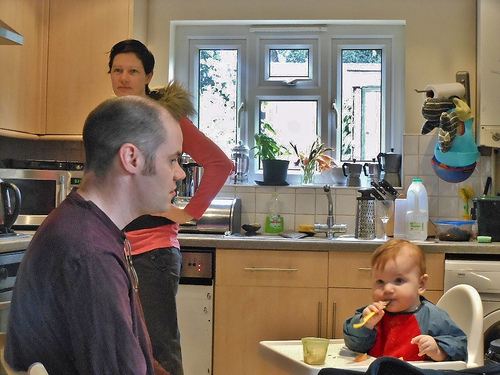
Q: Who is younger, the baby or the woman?
A: The baby is younger than the woman.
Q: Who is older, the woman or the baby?
A: The woman is older than the baby.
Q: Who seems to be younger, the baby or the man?
A: The baby is younger than the man.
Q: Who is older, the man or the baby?
A: The man is older than the baby.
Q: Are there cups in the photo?
A: Yes, there is a cup.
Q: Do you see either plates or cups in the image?
A: Yes, there is a cup.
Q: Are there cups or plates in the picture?
A: Yes, there is a cup.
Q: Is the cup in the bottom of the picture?
A: Yes, the cup is in the bottom of the image.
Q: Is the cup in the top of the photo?
A: No, the cup is in the bottom of the image.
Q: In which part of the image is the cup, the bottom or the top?
A: The cup is in the bottom of the image.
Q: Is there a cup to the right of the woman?
A: Yes, there is a cup to the right of the woman.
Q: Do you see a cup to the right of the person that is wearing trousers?
A: Yes, there is a cup to the right of the woman.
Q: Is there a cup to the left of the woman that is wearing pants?
A: No, the cup is to the right of the woman.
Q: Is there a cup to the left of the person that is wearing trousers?
A: No, the cup is to the right of the woman.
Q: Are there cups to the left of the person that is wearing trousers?
A: No, the cup is to the right of the woman.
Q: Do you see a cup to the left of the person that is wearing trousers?
A: No, the cup is to the right of the woman.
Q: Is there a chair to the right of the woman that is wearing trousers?
A: No, there is a cup to the right of the woman.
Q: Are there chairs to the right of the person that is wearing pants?
A: No, there is a cup to the right of the woman.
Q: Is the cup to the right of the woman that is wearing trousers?
A: Yes, the cup is to the right of the woman.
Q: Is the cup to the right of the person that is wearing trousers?
A: Yes, the cup is to the right of the woman.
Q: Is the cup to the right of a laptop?
A: No, the cup is to the right of the woman.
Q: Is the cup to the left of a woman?
A: No, the cup is to the right of a woman.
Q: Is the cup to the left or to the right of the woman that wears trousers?
A: The cup is to the right of the woman.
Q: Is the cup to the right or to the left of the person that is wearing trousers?
A: The cup is to the right of the woman.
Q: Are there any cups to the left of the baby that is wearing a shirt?
A: Yes, there is a cup to the left of the baby.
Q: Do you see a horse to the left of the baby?
A: No, there is a cup to the left of the baby.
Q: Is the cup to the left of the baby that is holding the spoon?
A: Yes, the cup is to the left of the baby.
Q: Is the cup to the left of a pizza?
A: No, the cup is to the left of the baby.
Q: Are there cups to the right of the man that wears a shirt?
A: Yes, there is a cup to the right of the man.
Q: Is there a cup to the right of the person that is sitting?
A: Yes, there is a cup to the right of the man.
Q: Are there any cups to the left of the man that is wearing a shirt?
A: No, the cup is to the right of the man.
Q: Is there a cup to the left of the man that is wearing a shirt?
A: No, the cup is to the right of the man.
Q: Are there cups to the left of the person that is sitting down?
A: No, the cup is to the right of the man.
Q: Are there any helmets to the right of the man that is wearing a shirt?
A: No, there is a cup to the right of the man.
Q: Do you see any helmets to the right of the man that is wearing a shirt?
A: No, there is a cup to the right of the man.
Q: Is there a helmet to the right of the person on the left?
A: No, there is a cup to the right of the man.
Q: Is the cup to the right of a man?
A: Yes, the cup is to the right of a man.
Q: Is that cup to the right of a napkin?
A: No, the cup is to the right of a man.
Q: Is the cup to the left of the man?
A: No, the cup is to the right of the man.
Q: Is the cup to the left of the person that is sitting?
A: No, the cup is to the right of the man.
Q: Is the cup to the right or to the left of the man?
A: The cup is to the right of the man.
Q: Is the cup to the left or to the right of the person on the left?
A: The cup is to the right of the man.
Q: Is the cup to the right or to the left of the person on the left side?
A: The cup is to the right of the man.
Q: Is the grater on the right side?
A: Yes, the grater is on the right of the image.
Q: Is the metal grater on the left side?
A: No, the grater is on the right of the image.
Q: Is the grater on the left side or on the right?
A: The grater is on the right of the image.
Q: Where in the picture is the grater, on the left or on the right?
A: The grater is on the right of the image.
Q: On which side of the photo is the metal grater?
A: The grater is on the right of the image.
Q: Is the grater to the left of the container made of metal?
A: Yes, the grater is made of metal.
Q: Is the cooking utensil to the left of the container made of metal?
A: Yes, the grater is made of metal.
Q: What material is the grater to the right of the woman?
A: The grater is made of metal.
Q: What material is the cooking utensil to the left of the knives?
A: The grater is made of metal.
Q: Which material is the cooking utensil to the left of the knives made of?
A: The grater is made of metal.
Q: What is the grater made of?
A: The grater is made of metal.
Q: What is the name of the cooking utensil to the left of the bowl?
A: The cooking utensil is a grater.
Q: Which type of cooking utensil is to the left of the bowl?
A: The cooking utensil is a grater.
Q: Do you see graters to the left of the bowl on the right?
A: Yes, there is a grater to the left of the bowl.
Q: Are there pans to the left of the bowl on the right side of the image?
A: No, there is a grater to the left of the bowl.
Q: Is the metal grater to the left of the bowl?
A: Yes, the grater is to the left of the bowl.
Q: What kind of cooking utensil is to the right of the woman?
A: The cooking utensil is a grater.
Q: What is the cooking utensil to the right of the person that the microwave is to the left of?
A: The cooking utensil is a grater.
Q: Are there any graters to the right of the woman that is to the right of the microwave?
A: Yes, there is a grater to the right of the woman.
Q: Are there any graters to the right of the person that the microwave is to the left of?
A: Yes, there is a grater to the right of the woman.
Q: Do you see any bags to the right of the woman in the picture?
A: No, there is a grater to the right of the woman.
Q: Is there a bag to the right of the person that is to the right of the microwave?
A: No, there is a grater to the right of the woman.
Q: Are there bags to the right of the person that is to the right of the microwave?
A: No, there is a grater to the right of the woman.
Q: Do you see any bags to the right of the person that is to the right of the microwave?
A: No, there is a grater to the right of the woman.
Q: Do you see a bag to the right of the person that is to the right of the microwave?
A: No, there is a grater to the right of the woman.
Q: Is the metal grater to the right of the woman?
A: Yes, the grater is to the right of the woman.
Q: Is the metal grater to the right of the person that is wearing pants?
A: Yes, the grater is to the right of the woman.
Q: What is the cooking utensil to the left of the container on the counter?
A: The cooking utensil is a grater.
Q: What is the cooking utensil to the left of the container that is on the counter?
A: The cooking utensil is a grater.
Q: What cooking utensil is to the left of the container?
A: The cooking utensil is a grater.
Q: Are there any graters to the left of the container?
A: Yes, there is a grater to the left of the container.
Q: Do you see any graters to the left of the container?
A: Yes, there is a grater to the left of the container.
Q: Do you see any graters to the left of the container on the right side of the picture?
A: Yes, there is a grater to the left of the container.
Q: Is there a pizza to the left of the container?
A: No, there is a grater to the left of the container.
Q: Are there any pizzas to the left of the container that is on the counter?
A: No, there is a grater to the left of the container.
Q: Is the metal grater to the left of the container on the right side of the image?
A: Yes, the grater is to the left of the container.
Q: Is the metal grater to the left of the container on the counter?
A: Yes, the grater is to the left of the container.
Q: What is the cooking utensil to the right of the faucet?
A: The cooking utensil is a grater.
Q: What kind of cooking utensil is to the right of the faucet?
A: The cooking utensil is a grater.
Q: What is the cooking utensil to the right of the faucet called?
A: The cooking utensil is a grater.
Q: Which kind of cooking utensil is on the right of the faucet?
A: The cooking utensil is a grater.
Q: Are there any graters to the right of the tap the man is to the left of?
A: Yes, there is a grater to the right of the tap.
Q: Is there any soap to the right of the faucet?
A: No, there is a grater to the right of the faucet.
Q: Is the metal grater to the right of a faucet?
A: Yes, the grater is to the right of a faucet.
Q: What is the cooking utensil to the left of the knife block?
A: The cooking utensil is a grater.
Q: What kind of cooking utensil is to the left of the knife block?
A: The cooking utensil is a grater.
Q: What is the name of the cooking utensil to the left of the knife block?
A: The cooking utensil is a grater.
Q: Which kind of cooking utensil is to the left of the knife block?
A: The cooking utensil is a grater.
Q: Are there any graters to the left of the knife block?
A: Yes, there is a grater to the left of the knife block.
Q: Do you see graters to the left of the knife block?
A: Yes, there is a grater to the left of the knife block.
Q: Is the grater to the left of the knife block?
A: Yes, the grater is to the left of the knife block.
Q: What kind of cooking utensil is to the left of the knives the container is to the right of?
A: The cooking utensil is a grater.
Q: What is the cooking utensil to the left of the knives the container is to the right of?
A: The cooking utensil is a grater.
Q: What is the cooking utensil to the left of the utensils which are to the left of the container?
A: The cooking utensil is a grater.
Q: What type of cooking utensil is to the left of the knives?
A: The cooking utensil is a grater.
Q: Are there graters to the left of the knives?
A: Yes, there is a grater to the left of the knives.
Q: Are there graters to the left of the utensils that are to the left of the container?
A: Yes, there is a grater to the left of the knives.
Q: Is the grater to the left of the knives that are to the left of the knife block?
A: Yes, the grater is to the left of the knives.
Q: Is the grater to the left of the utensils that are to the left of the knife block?
A: Yes, the grater is to the left of the knives.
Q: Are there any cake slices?
A: No, there are no cake slices.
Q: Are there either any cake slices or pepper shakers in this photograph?
A: No, there are no cake slices or pepper shakers.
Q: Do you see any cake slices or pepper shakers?
A: No, there are no cake slices or pepper shakers.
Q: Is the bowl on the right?
A: Yes, the bowl is on the right of the image.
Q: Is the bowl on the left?
A: No, the bowl is on the right of the image.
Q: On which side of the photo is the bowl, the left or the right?
A: The bowl is on the right of the image.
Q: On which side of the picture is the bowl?
A: The bowl is on the right of the image.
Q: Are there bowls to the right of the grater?
A: Yes, there is a bowl to the right of the grater.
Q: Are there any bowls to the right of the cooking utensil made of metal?
A: Yes, there is a bowl to the right of the grater.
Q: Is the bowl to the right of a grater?
A: Yes, the bowl is to the right of a grater.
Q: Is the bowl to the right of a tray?
A: No, the bowl is to the right of a grater.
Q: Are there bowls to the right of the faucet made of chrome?
A: Yes, there is a bowl to the right of the tap.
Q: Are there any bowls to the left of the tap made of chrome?
A: No, the bowl is to the right of the tap.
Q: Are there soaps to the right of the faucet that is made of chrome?
A: No, there is a bowl to the right of the tap.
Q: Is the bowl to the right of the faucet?
A: Yes, the bowl is to the right of the faucet.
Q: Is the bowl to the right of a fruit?
A: No, the bowl is to the right of the faucet.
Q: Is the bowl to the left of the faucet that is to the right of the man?
A: No, the bowl is to the right of the faucet.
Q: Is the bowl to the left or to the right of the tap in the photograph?
A: The bowl is to the right of the tap.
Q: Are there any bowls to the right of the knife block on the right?
A: Yes, there is a bowl to the right of the knife block.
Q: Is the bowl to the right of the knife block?
A: Yes, the bowl is to the right of the knife block.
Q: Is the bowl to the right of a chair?
A: No, the bowl is to the right of the knife block.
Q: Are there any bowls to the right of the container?
A: Yes, there is a bowl to the right of the container.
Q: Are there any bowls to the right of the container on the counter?
A: Yes, there is a bowl to the right of the container.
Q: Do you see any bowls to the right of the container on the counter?
A: Yes, there is a bowl to the right of the container.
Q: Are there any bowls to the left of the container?
A: No, the bowl is to the right of the container.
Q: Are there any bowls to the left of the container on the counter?
A: No, the bowl is to the right of the container.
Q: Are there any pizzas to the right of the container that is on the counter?
A: No, there is a bowl to the right of the container.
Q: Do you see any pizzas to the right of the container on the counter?
A: No, there is a bowl to the right of the container.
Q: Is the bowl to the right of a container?
A: Yes, the bowl is to the right of a container.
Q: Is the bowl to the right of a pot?
A: No, the bowl is to the right of a container.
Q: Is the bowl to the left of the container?
A: No, the bowl is to the right of the container.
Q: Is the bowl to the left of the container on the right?
A: No, the bowl is to the right of the container.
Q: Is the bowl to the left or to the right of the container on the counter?
A: The bowl is to the right of the container.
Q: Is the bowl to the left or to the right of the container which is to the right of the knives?
A: The bowl is to the right of the container.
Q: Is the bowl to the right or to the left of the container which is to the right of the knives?
A: The bowl is to the right of the container.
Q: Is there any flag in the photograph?
A: No, there are no flags.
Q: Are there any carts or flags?
A: No, there are no flags or carts.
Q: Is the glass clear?
A: Yes, the glass is clear.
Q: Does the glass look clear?
A: Yes, the glass is clear.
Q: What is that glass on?
A: The glass is on the counter.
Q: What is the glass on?
A: The glass is on the counter.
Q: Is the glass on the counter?
A: Yes, the glass is on the counter.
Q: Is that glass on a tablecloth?
A: No, the glass is on the counter.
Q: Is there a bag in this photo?
A: No, there are no bags.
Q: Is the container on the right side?
A: Yes, the container is on the right of the image.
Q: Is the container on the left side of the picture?
A: No, the container is on the right of the image.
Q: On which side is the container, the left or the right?
A: The container is on the right of the image.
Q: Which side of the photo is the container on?
A: The container is on the right of the image.